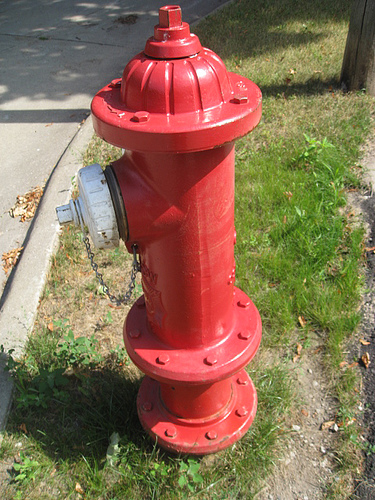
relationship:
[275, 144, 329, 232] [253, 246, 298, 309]
grass in grass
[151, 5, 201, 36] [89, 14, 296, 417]
bolt on top of hydrant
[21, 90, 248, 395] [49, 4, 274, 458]
concrete curb in front of hydrant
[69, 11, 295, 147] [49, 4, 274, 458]
cap on hydrant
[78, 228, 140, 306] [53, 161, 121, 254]
chain attached to cap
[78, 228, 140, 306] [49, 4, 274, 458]
chain attached to hydrant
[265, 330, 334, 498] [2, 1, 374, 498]
dirt on ground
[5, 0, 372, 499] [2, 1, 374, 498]
grass on ground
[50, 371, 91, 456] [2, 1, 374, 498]
grass on ground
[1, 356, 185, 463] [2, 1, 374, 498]
shadow on ground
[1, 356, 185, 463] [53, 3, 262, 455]
shadow of fire hydrant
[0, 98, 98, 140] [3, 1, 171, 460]
shadow on road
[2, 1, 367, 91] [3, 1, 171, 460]
shadow on road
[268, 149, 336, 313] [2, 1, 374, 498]
grass on ground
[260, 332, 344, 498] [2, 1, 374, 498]
patch on ground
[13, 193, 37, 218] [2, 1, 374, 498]
leaves on ground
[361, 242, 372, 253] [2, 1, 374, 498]
leaves on ground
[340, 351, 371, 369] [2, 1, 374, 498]
leaves on ground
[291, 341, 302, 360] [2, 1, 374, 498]
leaves on ground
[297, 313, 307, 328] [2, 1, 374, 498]
leaves on ground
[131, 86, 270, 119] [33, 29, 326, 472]
bolts on hydrant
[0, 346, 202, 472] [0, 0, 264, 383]
shadow on street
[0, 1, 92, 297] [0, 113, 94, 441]
road in front of concrete curb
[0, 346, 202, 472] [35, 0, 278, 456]
shadow of fire hydrant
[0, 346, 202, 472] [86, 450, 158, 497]
shadow on grass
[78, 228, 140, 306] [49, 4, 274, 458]
chain on hydrant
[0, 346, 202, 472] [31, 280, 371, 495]
shadow on ground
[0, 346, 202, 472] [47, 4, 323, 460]
shadow of hydrant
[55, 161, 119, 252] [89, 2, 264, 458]
cap on fire hydrant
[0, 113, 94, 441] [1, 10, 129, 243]
concrete curb on street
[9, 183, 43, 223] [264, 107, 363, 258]
leaves in grass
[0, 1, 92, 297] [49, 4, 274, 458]
road next to hydrant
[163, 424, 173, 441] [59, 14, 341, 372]
bolt on hydrant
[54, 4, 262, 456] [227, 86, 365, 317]
fire hydrant in grass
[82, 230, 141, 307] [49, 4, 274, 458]
chain hanging from hydrant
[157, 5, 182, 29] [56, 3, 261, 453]
bolt on hydrant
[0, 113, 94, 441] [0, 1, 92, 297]
concrete curb of road